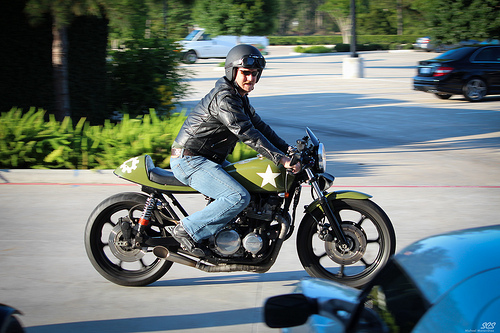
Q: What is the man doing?
A: Motorcycle.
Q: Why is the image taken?
A: Remembrance.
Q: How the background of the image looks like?
A: Blur.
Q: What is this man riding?
A: Motorcycle.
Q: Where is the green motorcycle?
A: Street.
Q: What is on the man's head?
A: Helmet.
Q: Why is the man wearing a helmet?
A: Safety.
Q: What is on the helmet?
A: Goggles.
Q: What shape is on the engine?
A: Star.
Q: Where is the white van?
A: Behind tree.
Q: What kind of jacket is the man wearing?
A: Leather.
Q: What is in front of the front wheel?
A: Car.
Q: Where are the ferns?
A: Across street.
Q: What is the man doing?
A: Riding a motorcycle.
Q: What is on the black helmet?
A: A pair of goggles.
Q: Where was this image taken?
A: In a parking lot.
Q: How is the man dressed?
A: In jeans and a leather jacket.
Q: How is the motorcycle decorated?
A: It has a white star and a gear shape on it.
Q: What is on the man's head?
A: A black helmet.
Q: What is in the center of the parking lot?
A: A street light with a cement base.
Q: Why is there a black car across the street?
A: It is parked in a parking lot.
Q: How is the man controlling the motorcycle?
A: With the throttle and brake on the handles.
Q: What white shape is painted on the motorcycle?
A: Star.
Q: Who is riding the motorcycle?
A: A man.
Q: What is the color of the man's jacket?
A: Black.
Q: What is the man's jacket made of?
A: Leather.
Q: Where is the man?
A: On the motorcycle.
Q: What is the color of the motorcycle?
A: Green.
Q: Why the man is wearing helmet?
A: For safety.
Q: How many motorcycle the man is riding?
A: One.